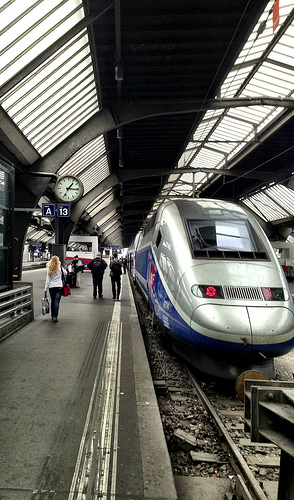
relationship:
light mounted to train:
[206, 286, 216, 297] [122, 194, 292, 380]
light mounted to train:
[261, 288, 270, 298] [122, 194, 292, 380]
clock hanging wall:
[53, 172, 84, 204] [0, 5, 117, 322]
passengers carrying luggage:
[44, 255, 68, 323] [36, 288, 49, 319]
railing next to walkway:
[0, 269, 42, 344] [1, 258, 176, 498]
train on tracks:
[122, 184, 292, 360] [180, 360, 276, 498]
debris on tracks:
[160, 402, 213, 456] [177, 357, 282, 498]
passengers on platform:
[38, 244, 126, 324] [1, 233, 162, 495]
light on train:
[204, 284, 216, 296] [122, 194, 292, 380]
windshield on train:
[182, 215, 274, 268] [122, 194, 292, 380]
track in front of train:
[176, 360, 280, 498] [122, 194, 292, 380]